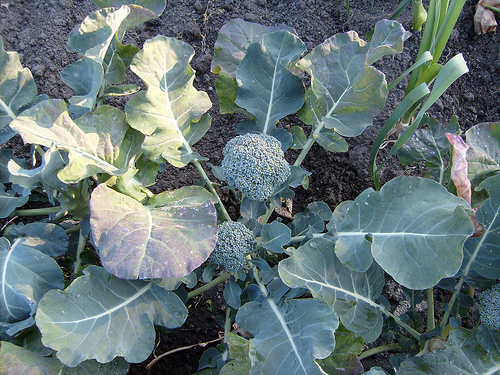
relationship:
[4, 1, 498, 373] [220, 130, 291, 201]
plant has broccoli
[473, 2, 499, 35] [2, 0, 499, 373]
rock in dirt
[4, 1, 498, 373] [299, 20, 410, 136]
plant has a leaf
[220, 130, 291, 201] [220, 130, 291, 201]
broccoli has a broccoli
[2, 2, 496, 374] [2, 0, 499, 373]
ground has dirt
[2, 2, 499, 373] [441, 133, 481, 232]
picture has a flower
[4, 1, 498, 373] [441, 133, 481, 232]
plant has a flower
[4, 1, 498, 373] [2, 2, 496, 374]
plant on ground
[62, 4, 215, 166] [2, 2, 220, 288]
leaves are getting sunshin